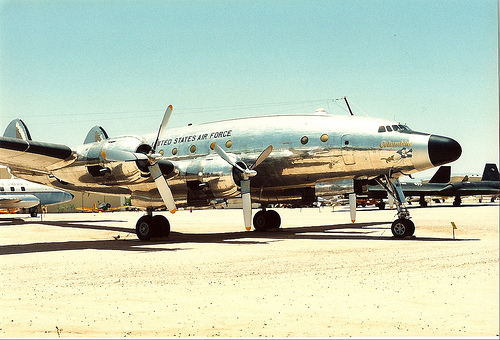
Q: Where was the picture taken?
A: On a plane yard.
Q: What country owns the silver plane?
A: United States.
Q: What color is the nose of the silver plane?
A: Black.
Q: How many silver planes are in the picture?
A: 1.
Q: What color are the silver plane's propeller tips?
A: Yellow.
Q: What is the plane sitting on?
A: Dirt.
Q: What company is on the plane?
A: Air Force.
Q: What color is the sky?
A: Blue.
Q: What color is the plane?
A: Silver.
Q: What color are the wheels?
A: Black.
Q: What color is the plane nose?
A: Black.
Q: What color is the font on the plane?
A: Black.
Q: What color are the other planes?
A: Black.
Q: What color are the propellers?
A: Silver.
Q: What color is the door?
A: Silver.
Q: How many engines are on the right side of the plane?
A: Two.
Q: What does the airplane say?
A: US air force.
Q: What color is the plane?
A: Silver.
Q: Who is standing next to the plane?
A: No one.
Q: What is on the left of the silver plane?
A: Propellers.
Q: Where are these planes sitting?
A: Airport.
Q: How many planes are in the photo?
A: 4.